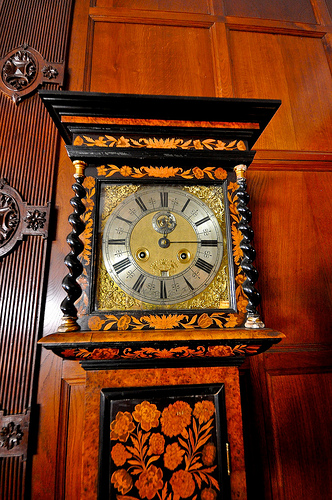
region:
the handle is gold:
[221, 447, 230, 462]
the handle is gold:
[224, 446, 228, 464]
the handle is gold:
[224, 452, 232, 467]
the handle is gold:
[222, 450, 230, 471]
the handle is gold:
[221, 441, 227, 468]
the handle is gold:
[216, 451, 226, 473]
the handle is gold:
[224, 457, 232, 477]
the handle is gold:
[227, 450, 234, 473]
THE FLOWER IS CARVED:
[13, 426, 16, 447]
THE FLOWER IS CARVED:
[9, 432, 14, 444]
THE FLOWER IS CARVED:
[13, 436, 21, 442]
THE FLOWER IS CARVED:
[8, 434, 34, 457]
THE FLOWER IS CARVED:
[0, 413, 6, 432]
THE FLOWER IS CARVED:
[2, 425, 19, 445]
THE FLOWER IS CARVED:
[14, 428, 23, 453]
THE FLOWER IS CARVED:
[16, 426, 25, 446]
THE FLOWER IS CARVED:
[15, 431, 24, 443]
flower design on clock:
[85, 391, 225, 494]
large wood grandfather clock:
[53, 151, 267, 497]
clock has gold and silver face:
[100, 191, 232, 314]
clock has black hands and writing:
[152, 215, 214, 254]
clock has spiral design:
[56, 164, 89, 324]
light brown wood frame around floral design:
[83, 360, 246, 437]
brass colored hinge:
[217, 439, 236, 480]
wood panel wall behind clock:
[225, 140, 330, 498]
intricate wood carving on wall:
[2, 172, 45, 389]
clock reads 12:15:
[151, 200, 220, 261]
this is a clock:
[83, 159, 239, 315]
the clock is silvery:
[98, 186, 219, 307]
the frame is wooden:
[69, 97, 236, 176]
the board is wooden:
[270, 196, 320, 282]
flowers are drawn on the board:
[123, 396, 210, 498]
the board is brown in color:
[278, 193, 321, 265]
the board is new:
[0, 114, 44, 163]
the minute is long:
[169, 234, 200, 247]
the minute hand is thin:
[172, 238, 194, 247]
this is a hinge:
[221, 441, 234, 474]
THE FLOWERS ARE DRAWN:
[177, 450, 189, 474]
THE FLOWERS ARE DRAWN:
[176, 445, 196, 496]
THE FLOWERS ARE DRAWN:
[151, 438, 178, 472]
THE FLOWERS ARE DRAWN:
[163, 463, 187, 484]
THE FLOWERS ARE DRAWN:
[156, 457, 180, 484]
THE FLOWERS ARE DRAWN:
[154, 462, 176, 479]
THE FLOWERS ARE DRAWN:
[162, 470, 196, 496]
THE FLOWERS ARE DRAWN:
[166, 449, 183, 469]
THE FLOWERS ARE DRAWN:
[169, 462, 190, 492]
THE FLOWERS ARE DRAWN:
[176, 469, 201, 491]